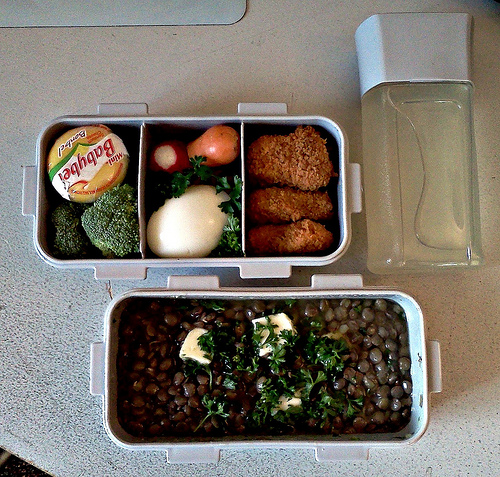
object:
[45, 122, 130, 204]
cheese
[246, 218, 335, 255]
nuggets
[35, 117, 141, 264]
tray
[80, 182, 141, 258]
broccoli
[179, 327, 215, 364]
butter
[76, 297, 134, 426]
dish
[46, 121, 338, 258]
food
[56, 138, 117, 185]
print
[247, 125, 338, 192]
meat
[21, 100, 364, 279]
container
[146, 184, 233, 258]
egg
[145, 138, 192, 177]
radish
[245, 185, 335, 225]
chicken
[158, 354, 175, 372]
beans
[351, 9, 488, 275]
container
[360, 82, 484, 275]
water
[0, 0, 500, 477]
table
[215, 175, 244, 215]
parsley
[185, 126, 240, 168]
radishes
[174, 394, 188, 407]
lentils